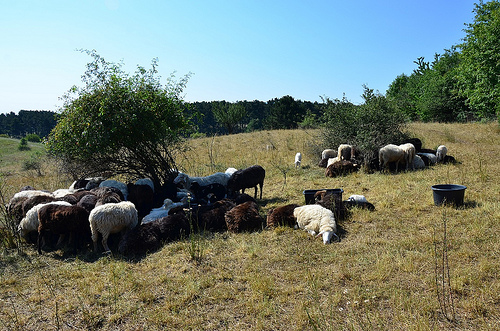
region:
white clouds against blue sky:
[17, 12, 111, 39]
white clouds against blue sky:
[12, 41, 57, 72]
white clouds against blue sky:
[127, 21, 184, 35]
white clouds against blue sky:
[225, 13, 336, 50]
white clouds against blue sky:
[218, 49, 350, 87]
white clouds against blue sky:
[341, 23, 418, 63]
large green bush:
[81, 99, 162, 141]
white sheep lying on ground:
[290, 201, 340, 255]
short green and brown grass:
[205, 263, 313, 304]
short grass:
[371, 212, 438, 297]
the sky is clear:
[284, 32, 351, 84]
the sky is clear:
[110, 26, 179, 61]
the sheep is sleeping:
[273, 193, 358, 262]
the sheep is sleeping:
[222, 182, 289, 242]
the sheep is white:
[277, 196, 341, 248]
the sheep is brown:
[222, 189, 272, 240]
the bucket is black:
[399, 179, 464, 213]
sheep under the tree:
[40, 104, 220, 225]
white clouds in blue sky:
[11, 15, 50, 50]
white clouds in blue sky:
[14, 43, 35, 79]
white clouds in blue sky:
[65, 13, 157, 50]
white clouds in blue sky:
[154, 13, 244, 58]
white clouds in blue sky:
[192, 45, 243, 80]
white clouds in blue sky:
[228, 20, 287, 58]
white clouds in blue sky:
[226, 50, 294, 82]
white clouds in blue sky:
[294, 7, 351, 49]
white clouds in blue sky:
[279, 54, 349, 85]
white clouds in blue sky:
[323, 4, 387, 46]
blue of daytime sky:
[1, 2, 478, 111]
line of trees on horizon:
[1, 93, 353, 140]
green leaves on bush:
[51, 48, 192, 163]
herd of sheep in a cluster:
[14, 159, 267, 249]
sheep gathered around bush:
[319, 97, 446, 177]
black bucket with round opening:
[430, 180, 468, 210]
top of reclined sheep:
[291, 203, 338, 244]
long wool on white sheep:
[86, 202, 136, 239]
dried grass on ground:
[2, 123, 496, 328]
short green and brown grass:
[25, 255, 95, 307]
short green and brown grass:
[141, 248, 230, 317]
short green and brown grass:
[231, 233, 284, 287]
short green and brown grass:
[315, 245, 377, 310]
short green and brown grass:
[368, 220, 421, 275]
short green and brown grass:
[393, 251, 475, 304]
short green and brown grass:
[210, 145, 240, 153]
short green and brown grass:
[450, 122, 479, 160]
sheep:
[287, 203, 320, 248]